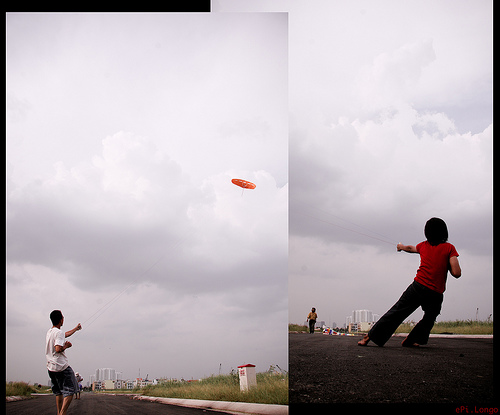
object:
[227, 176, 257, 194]
kite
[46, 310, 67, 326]
head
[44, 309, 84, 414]
man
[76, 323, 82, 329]
hand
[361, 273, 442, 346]
pants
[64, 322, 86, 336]
arm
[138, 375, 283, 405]
grass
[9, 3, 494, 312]
sky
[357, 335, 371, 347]
foot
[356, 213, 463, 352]
man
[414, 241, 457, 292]
shirt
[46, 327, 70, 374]
shirt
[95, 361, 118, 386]
building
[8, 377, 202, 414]
road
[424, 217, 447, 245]
hair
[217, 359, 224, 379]
crane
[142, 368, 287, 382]
skyline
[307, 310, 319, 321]
shirt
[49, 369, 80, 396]
jeans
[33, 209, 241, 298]
cloud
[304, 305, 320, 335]
man